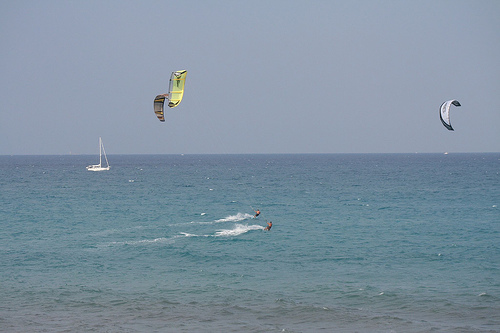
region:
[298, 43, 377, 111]
the sky is blue in color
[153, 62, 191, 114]
this is a kite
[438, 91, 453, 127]
the kite is white in color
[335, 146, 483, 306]
this is a water body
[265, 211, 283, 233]
this is a man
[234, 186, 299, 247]
the men are two in number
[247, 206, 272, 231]
two men water skiing in the ocean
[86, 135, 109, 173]
the boat floating in the ocean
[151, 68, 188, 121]
two kites flying next to each other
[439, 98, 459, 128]
another kite flying alone in the sky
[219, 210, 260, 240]
the water splashing up from the men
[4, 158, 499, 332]
the calm ocean the men are having fun in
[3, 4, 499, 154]
the blue sky with no clouds in it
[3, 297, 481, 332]
the darker part of the water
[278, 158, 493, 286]
the still water next to the men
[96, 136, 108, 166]
the part of the boat meant for the sail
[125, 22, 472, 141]
kites in the sky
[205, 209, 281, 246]
the people are swimming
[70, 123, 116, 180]
boat on the ocean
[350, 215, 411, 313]
large body of water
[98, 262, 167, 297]
the water is calm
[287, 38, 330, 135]
the sky is clear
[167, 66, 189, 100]
the kite is yellow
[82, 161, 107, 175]
the boat is white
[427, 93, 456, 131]
the kite is white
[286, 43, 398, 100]
the sky is clear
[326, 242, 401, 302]
the water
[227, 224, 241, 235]
the water is white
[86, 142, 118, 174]
a boat in the water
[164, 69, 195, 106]
kites in the sky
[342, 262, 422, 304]
the water is blue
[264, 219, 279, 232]
a person in the water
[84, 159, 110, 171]
the boat is white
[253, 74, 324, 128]
the sky is blue and clear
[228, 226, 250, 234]
a splash of water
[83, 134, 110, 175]
boat in the ocean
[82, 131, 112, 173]
boat's mast is not up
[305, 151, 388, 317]
water is different shades of blue